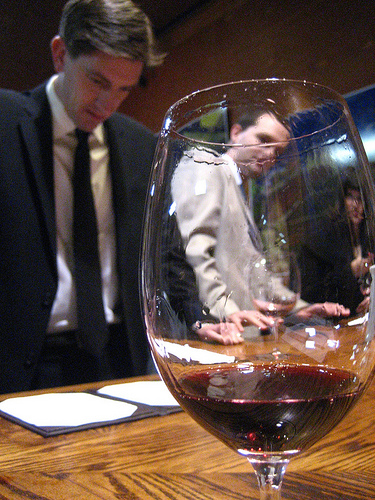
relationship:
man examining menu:
[0, 0, 243, 397] [0, 379, 186, 437]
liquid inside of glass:
[166, 363, 364, 451] [136, 77, 374, 500]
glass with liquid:
[136, 77, 374, 500] [166, 363, 364, 451]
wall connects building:
[139, 0, 374, 147] [2, 5, 373, 498]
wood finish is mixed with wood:
[3, 310, 374, 499] [0, 317, 374, 499]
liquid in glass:
[166, 363, 364, 451] [136, 77, 374, 500]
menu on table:
[0, 379, 186, 437] [0, 175, 373, 494]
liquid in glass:
[174, 363, 365, 451] [136, 72, 364, 491]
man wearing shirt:
[2, 1, 239, 396] [43, 72, 124, 337]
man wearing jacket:
[168, 103, 350, 331] [169, 144, 313, 319]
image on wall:
[186, 106, 222, 131] [1, 0, 374, 253]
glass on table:
[136, 72, 364, 491] [0, 310, 374, 498]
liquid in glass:
[166, 363, 364, 451] [128, 48, 365, 499]